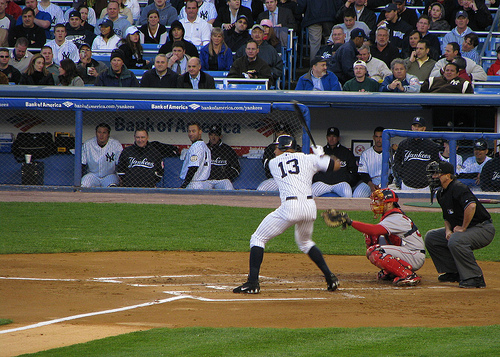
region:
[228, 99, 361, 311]
baseball player at bat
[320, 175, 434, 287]
catcher in a baseball game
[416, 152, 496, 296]
umpire at a baseball game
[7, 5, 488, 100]
spectators in the bleachers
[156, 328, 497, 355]
green grass at a baseball field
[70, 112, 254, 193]
four men in a dugout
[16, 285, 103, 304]
dirt ground at a field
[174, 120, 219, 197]
Derek Jeter watching batter at bat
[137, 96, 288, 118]
logo on a fence pole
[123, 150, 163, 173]
logo of the NY Yankees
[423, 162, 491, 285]
An umpire dressed in black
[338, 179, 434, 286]
A catcher in position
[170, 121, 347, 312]
A batter in the batter's box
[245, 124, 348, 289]
Baseball player number 13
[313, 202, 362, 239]
A catcher's mitt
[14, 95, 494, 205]
The dugout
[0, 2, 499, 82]
Baseball fans in the stands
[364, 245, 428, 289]
Catcher's red shin guards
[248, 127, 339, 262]
A baseball player wearing a batting helmet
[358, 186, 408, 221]
A catcher's mask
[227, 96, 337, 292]
batter about to swing bat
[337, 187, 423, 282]
catcher squatting behind hitter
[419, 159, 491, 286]
umpire squatting behind catcher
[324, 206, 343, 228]
baseball catcher's mitt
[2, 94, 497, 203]
dugout full of baseball players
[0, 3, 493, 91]
rows of spectators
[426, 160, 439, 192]
black umpire's face mask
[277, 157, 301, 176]
number 13 on white jersey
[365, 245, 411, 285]
red catcher's equiptment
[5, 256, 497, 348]
brown dirt on baseball field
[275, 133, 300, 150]
blue helmet on mans head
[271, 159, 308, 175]
number thirteen on mans shirt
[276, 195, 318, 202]
black belt on mans waist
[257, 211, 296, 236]
man wears white pants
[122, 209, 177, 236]
green grass in field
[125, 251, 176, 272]
brown dirt in field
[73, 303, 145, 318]
white stripe in dirt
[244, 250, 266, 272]
man wears blue socks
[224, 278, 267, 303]
man wears black sneakers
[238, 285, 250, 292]
White nike sign on sneakers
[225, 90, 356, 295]
the player is swinging the bat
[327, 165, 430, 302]
the catcher is ready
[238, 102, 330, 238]
the number thirteen on the shirt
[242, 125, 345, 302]
the uniform is stiped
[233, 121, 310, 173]
the man is wearing a helmet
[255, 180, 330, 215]
the man is wearing a belt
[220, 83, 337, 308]
the player is at home base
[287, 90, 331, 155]
the bat is black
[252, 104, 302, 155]
the helmet is black and shiny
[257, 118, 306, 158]
light is reflecting off of the helmet